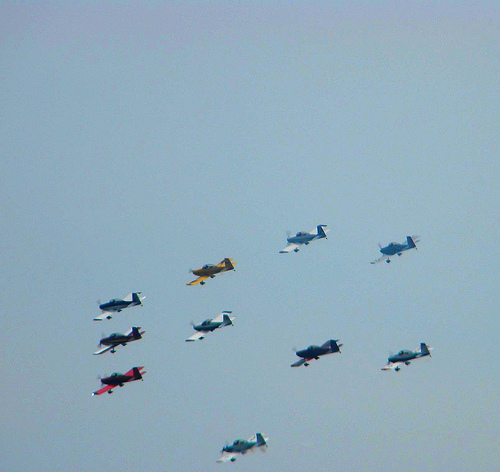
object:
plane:
[284, 327, 345, 368]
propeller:
[97, 300, 104, 314]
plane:
[215, 419, 275, 467]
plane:
[85, 321, 154, 355]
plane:
[182, 309, 241, 344]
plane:
[91, 364, 148, 399]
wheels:
[380, 251, 404, 263]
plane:
[364, 228, 425, 260]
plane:
[86, 286, 150, 327]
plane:
[373, 337, 438, 377]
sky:
[0, 0, 499, 472]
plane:
[274, 213, 347, 256]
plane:
[90, 357, 160, 405]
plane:
[183, 253, 238, 290]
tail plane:
[245, 418, 270, 450]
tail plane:
[413, 331, 431, 358]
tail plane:
[322, 323, 349, 355]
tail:
[131, 361, 149, 385]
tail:
[219, 309, 238, 327]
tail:
[327, 333, 345, 356]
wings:
[367, 254, 388, 267]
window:
[297, 228, 309, 239]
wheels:
[393, 360, 412, 374]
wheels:
[300, 354, 320, 367]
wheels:
[198, 272, 216, 288]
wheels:
[105, 382, 123, 395]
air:
[0, 0, 490, 470]